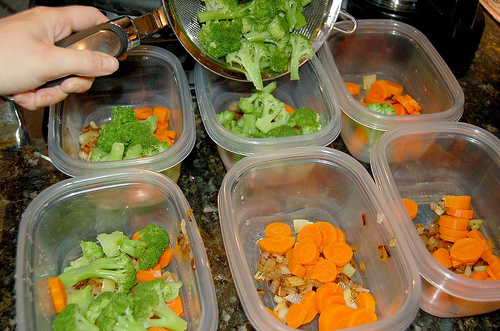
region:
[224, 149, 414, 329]
Container has sliced carrots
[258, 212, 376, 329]
Sliced carrots are cooked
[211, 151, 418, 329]
Container is clear plastic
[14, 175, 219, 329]
Container is clear plastic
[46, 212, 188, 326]
Container has broccoli and carrots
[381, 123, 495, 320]
Container is clear plastic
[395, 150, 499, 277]
Container has sliced carrots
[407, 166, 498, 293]
Orange carrots are cooked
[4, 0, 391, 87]
Woman holding a strainer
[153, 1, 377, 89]
Strainer has cooked broccoli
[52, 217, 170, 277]
Broccoli and carrots mixed together.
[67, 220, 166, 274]
The broccoli is green.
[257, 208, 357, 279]
The carrots are orange.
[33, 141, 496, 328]
Clear containers with veggies.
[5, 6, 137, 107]
A person holding a strainer.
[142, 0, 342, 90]
The strainer is made of stainless steel.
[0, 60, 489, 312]
The containers are on a marble table.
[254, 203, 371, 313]
Onions are in with the carrots.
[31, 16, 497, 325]
Six containers are on the table.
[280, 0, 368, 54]
The strainer has a metal loop on it.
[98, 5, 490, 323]
Six plastic containers for food.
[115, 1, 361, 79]
Kitchen strainer.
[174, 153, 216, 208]
Marble Counter top.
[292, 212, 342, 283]
Sliced carrots.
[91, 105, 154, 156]
Broccoli Florets prepared for lunch.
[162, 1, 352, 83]
Broccoli Florets placed in a strainer.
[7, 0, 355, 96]
Person's hand holding strainer while draining broccoli.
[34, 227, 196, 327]
Mixed vegetables, broccoli and carrots.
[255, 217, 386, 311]
Mixed vegetables, broccoli and mushrooms.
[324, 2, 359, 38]
Hook on side of food strainer.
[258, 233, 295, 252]
a sliced carrot on a plate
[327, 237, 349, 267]
a sliced carrot on a plate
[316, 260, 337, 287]
a sliced carrot on a plate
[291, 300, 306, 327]
a sliced carrot on a plate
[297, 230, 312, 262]
a sliced carrot on a plate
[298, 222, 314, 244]
a sliced carrot on a plate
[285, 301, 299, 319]
a sliced carrot on a plate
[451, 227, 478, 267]
a sliced carrot on a plate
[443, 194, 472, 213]
a sliced carrot on a plate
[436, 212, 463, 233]
a sliced carrot on a plate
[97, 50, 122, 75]
the finger nail of a person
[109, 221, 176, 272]
a piece of green broccoli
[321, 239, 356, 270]
an orange slice of carrot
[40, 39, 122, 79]
the thumb of a person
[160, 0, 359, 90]
a metal strainer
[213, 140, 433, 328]
a clear plastic dish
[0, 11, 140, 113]
the handle of a strainer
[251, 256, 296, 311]
grilled onions under the carrots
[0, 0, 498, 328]
a bray marble counter top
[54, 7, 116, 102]
the finger of the person